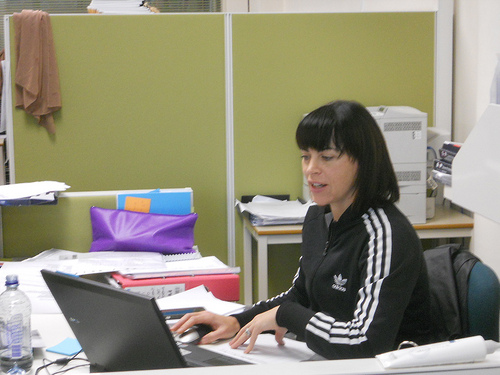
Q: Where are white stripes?
A: On black sweater.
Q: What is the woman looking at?
A: Laptop computer.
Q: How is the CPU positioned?
A: Upright.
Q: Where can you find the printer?
A: Table.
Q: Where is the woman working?
A: Office.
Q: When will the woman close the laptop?
A: Done working.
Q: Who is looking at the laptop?
A: Lady.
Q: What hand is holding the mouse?
A: Right hand.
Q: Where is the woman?
A: Cubicle.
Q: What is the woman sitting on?
A: Green chair.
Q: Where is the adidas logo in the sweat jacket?
A: On the left side.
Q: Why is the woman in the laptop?
A: Working.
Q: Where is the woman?
A: At an office.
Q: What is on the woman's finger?
A: A ring.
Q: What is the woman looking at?
A: A computer.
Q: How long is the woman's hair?
A: Shoulder length.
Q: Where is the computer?
A: On the desk.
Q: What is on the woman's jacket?
A: White stripes.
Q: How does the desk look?
A: Messy.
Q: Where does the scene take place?
A: In an office.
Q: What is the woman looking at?
A: A laptop.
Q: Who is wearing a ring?
A: A woman.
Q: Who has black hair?
A: The lady.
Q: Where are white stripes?
A: On black sweater.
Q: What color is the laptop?
A: Black.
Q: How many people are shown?
A: One.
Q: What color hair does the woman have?
A: Black.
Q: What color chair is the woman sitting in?
A: Blue.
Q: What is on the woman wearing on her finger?
A: Ring.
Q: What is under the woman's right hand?
A: Mouse.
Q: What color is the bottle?
A: Clear.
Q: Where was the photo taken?
A: At an office cubicle.